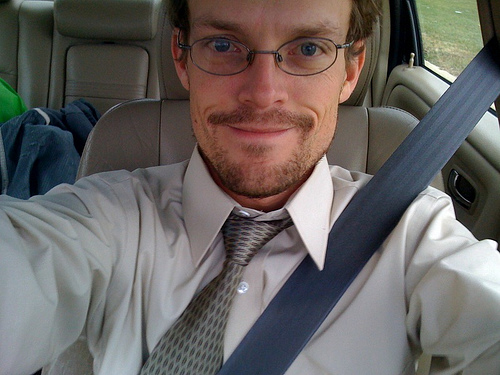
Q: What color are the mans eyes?
A: Blue.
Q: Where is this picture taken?
A: In a car.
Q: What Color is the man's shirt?
A: Beige.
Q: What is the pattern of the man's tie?
A: Diamond.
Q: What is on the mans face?
A: Glasses.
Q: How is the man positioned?
A: Sitting.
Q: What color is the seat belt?
A: Blue.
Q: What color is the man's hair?
A: Blonde.